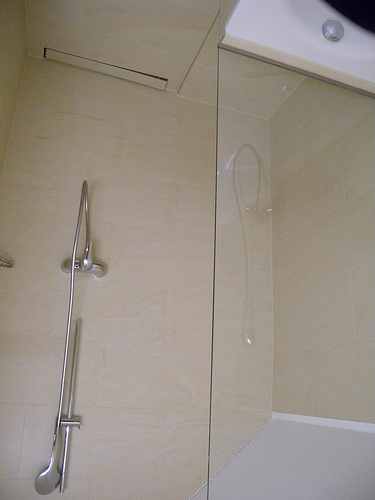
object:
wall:
[0, 0, 222, 499]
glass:
[207, 48, 372, 498]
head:
[37, 417, 65, 499]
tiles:
[106, 402, 181, 489]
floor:
[191, 418, 374, 497]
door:
[207, 46, 372, 497]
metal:
[55, 414, 81, 430]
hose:
[57, 178, 90, 415]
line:
[191, 416, 275, 499]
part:
[45, 434, 91, 500]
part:
[234, 397, 344, 464]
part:
[169, 308, 345, 355]